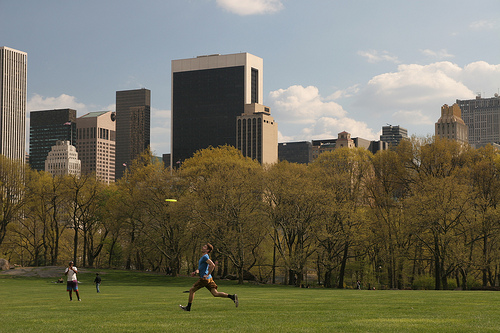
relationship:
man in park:
[182, 242, 242, 313] [0, 260, 494, 331]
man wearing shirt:
[66, 263, 82, 305] [63, 265, 78, 282]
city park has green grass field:
[3, 146, 481, 330] [0, 246, 498, 332]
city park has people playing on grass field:
[3, 146, 481, 330] [0, 246, 498, 332]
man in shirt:
[182, 225, 235, 317] [194, 249, 214, 279]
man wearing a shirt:
[182, 242, 242, 313] [197, 254, 213, 279]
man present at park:
[60, 261, 82, 299] [91, 127, 471, 283]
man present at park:
[182, 242, 242, 313] [91, 127, 471, 283]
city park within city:
[0, 135, 499, 330] [1, 0, 498, 330]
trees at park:
[223, 171, 420, 283] [354, 264, 445, 327]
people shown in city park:
[51, 240, 245, 315] [0, 135, 499, 330]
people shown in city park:
[346, 280, 378, 292] [0, 135, 499, 330]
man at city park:
[182, 242, 242, 313] [0, 135, 499, 330]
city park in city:
[0, 135, 499, 330] [1, 0, 498, 330]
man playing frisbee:
[182, 242, 242, 313] [156, 160, 193, 202]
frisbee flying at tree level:
[158, 193, 179, 207] [43, 165, 480, 228]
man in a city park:
[182, 242, 242, 313] [3, 146, 481, 330]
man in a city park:
[60, 261, 82, 299] [3, 146, 481, 330]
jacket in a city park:
[91, 275, 104, 284] [3, 146, 481, 330]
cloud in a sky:
[0, 0, 499, 119] [2, 6, 484, 86]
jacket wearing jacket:
[91, 275, 104, 284] [91, 274, 107, 285]